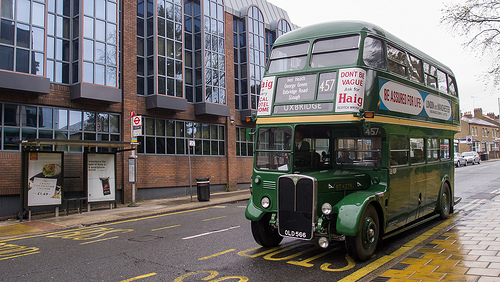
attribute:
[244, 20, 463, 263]
bus — double decker, green, dark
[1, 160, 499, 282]
street — dark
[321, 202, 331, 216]
headlight — round, white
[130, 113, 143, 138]
sign — red, whie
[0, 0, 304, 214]
building — brick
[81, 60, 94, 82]
window — glass, big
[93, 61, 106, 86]
window — glass, big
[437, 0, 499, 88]
tree — leafless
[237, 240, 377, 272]
word — yellow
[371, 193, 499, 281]
sidewalk — yellow brick, yellow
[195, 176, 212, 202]
trash can — black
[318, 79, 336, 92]
number — white, 4573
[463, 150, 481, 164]
car — parked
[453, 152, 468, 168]
car — parked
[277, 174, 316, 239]
grill — black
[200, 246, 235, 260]
line — yellow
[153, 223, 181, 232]
line — yellow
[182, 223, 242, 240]
line — white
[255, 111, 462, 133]
stripe — yellow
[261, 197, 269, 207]
headlight — round, white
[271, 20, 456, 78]
roof — curved